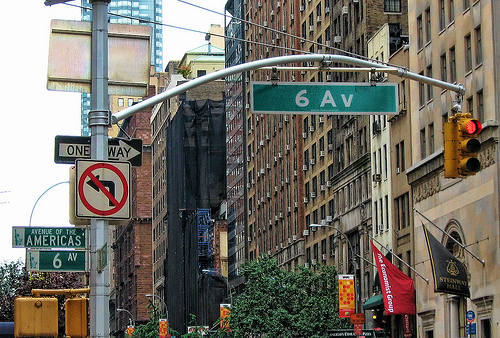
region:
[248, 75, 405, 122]
green and white sign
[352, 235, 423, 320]
red and white sign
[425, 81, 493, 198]
traffic light is red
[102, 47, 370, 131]
sign on grey pole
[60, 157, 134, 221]
red and black no turn sign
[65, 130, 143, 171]
black and white sign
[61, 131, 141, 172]
white arrow on sign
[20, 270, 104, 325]
yellow pedestrian crossing signs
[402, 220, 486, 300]
black and gold flag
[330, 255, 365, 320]
red and orange banners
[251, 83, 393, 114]
a street sign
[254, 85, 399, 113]
the sign is green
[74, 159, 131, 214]
a red and white sign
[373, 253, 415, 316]
a red flag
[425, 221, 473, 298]
a black flag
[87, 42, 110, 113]
a metal pole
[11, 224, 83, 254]
the green street sign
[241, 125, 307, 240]
a brown building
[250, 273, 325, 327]
the tree is green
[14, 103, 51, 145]
the sky is clear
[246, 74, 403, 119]
Green street sign on the pole with the traffic light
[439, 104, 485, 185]
Street light with the red light on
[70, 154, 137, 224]
White no left turn sign on the pole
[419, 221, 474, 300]
Black flag with gold lettering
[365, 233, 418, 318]
Red flag with white lettering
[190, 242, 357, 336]
Large green trees behind the flags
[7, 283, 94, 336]
Back of yellow walk don't walk lights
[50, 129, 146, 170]
Black one way road sign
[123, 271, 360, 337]
Four orange and yellow banners in front of the buildings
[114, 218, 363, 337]
Four street lamps in front of the buildings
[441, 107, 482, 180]
A hanging traffic light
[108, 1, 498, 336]
A row of large buildigns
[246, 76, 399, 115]
A green and white street sign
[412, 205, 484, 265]
A metal flag pole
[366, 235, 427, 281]
A metal flag pole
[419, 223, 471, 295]
A black and gold flag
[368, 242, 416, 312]
a red and white flag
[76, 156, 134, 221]
A no left turn sign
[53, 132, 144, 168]
A one way street sign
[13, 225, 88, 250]
A green and white street sign